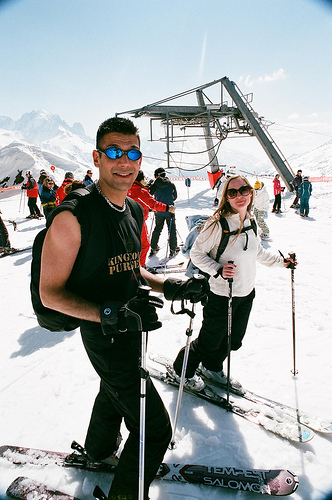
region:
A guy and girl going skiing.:
[27, 110, 290, 493]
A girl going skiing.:
[178, 161, 313, 426]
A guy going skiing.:
[18, 111, 191, 498]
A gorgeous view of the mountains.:
[1, 104, 92, 168]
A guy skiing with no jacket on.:
[29, 108, 198, 443]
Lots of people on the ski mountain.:
[4, 153, 101, 226]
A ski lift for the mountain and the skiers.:
[129, 59, 329, 228]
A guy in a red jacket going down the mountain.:
[6, 160, 42, 220]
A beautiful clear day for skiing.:
[23, 47, 325, 279]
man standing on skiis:
[28, 109, 185, 492]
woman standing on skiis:
[180, 163, 264, 412]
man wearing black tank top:
[26, 102, 201, 486]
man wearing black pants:
[18, 99, 206, 492]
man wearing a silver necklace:
[19, 104, 197, 484]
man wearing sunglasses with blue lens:
[22, 117, 214, 485]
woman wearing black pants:
[187, 166, 278, 415]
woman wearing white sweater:
[180, 164, 259, 413]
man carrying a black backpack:
[29, 116, 181, 482]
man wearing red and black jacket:
[18, 166, 42, 224]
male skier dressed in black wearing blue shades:
[29, 115, 212, 498]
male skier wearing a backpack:
[27, 114, 212, 498]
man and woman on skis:
[0, 115, 331, 499]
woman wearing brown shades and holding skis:
[146, 175, 331, 444]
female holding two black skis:
[166, 172, 302, 407]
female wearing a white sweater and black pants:
[170, 171, 299, 392]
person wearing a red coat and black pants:
[270, 172, 285, 215]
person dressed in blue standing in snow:
[297, 175, 314, 218]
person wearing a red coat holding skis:
[17, 169, 44, 219]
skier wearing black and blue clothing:
[147, 167, 181, 259]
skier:
[50, 88, 165, 462]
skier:
[192, 170, 267, 395]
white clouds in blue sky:
[253, 3, 306, 68]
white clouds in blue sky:
[148, 16, 196, 61]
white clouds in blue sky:
[30, 33, 89, 73]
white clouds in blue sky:
[84, 33, 130, 86]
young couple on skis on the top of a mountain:
[25, 107, 288, 482]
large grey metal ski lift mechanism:
[114, 73, 304, 197]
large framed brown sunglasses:
[223, 184, 254, 200]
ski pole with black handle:
[281, 251, 300, 387]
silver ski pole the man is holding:
[126, 330, 155, 496]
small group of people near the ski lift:
[265, 163, 321, 218]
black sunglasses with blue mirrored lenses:
[98, 144, 144, 163]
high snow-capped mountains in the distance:
[5, 103, 84, 160]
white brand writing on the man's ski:
[197, 461, 272, 498]